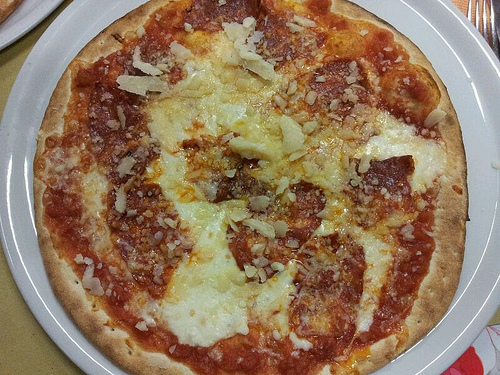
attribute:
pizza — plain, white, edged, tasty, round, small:
[63, 15, 473, 363]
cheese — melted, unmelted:
[137, 38, 303, 160]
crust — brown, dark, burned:
[306, 2, 485, 213]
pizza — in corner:
[1, 4, 43, 35]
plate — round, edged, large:
[39, 10, 474, 372]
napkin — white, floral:
[449, 333, 475, 374]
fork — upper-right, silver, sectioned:
[463, 5, 497, 42]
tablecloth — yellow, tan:
[0, 260, 74, 373]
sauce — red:
[104, 7, 239, 119]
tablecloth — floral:
[462, 330, 496, 374]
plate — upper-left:
[0, 5, 64, 54]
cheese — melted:
[160, 203, 240, 343]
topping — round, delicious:
[225, 188, 370, 354]